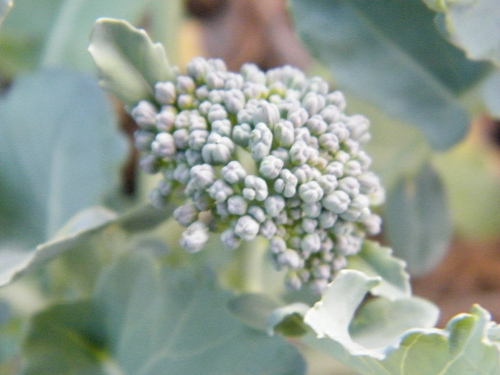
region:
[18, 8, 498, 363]
the buds are closed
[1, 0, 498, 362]
the leaves are green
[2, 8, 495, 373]
the picture is in a garden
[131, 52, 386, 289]
the flower has not bloomed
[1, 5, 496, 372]
the scene is daytime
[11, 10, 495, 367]
the leaves are curved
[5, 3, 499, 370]
the leaves are succulent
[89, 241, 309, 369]
the leaf is veined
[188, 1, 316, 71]
there is a brown object behind plant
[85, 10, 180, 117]
the leaf is small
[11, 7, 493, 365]
Vegetable is green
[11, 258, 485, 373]
Big leaves of broccoli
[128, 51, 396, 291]
Broccoli growing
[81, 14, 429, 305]
Two small leaves near florets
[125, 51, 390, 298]
Edible part of broccoli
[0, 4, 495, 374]
Big leaves around head of broccoli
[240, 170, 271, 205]
Floret of broccoli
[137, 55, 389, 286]
Floret of broccoli are green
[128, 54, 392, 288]
Floret of broccoli are small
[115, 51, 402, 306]
Many florets of broccoli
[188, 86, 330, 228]
bunch of purple flowers are seen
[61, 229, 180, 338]
leaves are seen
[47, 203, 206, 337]
leaves are green in color.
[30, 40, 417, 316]
daytime picture.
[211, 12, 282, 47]
one person is seen behind the plant.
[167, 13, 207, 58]
yellow color dress.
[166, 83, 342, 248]
buds are in bunch.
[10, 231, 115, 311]
edges of the leaves are irregular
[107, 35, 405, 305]
buds are at the tip of the plant.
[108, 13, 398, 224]
sunlight reflection.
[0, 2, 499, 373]
the plant is green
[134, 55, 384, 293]
the plant has buds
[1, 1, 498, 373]
the leaves look velvety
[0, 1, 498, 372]
a photo of plants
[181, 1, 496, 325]
the background is brown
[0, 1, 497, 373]
the leaves have shadows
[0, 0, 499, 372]
the plant is light green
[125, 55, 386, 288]
the plant has buds blooming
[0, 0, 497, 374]
the ground is brown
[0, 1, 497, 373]
the leaves have lines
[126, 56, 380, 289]
A white cluster of tiny buds.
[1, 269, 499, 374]
The pale green leaves.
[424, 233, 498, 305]
Red leaves of the plant.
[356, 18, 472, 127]
A darker green leaf.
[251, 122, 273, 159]
One white tiny bud.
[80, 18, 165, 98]
One light green leaf.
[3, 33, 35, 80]
A distant green area.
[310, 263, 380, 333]
A white leaf below cluster.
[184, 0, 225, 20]
A brown area above the cluster.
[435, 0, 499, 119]
The white petals of a flower.